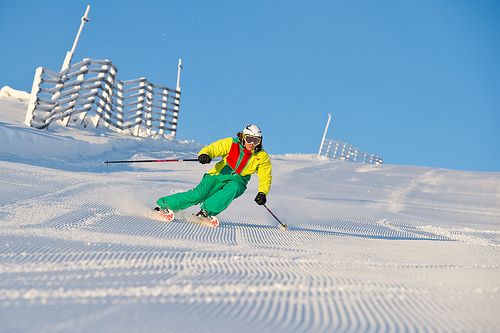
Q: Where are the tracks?
A: In the snow.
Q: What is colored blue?
A: The sky.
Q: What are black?
A: The two ski poles.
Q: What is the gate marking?
A: A no skiing area.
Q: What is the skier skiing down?
A: A mountain.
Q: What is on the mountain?
A: White snow.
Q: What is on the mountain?
A: White snow.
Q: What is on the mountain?
A: White snow.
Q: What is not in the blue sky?
A: Clouds.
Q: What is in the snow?
A: A fence.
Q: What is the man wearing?
A: A colorful outfit.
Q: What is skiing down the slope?
A: The person skiing.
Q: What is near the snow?
A: The white wooden fence.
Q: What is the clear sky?
A: Beautiful and blue.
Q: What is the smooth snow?
A: Down hill.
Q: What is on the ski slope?
A: The downhill skier.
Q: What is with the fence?
A: The ski trail markers.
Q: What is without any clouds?
A: The blue sky.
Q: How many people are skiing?
A: One.